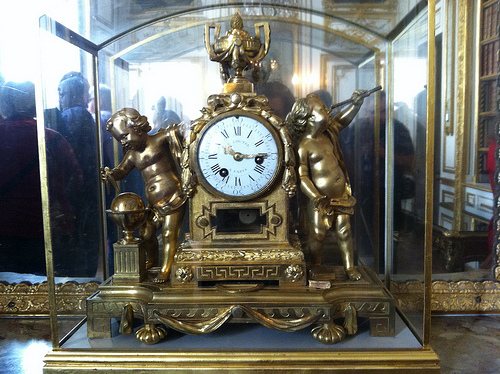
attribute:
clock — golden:
[169, 99, 302, 287]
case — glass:
[23, 0, 441, 372]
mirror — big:
[0, 0, 490, 299]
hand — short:
[214, 140, 233, 154]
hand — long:
[241, 150, 274, 166]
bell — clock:
[231, 207, 268, 229]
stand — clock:
[64, 235, 404, 345]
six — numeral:
[229, 171, 247, 190]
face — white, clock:
[191, 129, 284, 191]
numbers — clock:
[204, 126, 279, 198]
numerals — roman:
[194, 122, 284, 190]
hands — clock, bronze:
[220, 142, 267, 159]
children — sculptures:
[118, 119, 203, 267]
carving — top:
[200, 20, 280, 79]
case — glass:
[456, 320, 482, 355]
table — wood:
[441, 312, 482, 361]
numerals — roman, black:
[210, 135, 279, 185]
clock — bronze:
[114, 42, 413, 350]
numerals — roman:
[208, 125, 260, 176]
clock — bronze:
[79, 8, 420, 345]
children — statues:
[113, 109, 203, 255]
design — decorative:
[190, 254, 290, 277]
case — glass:
[40, 0, 433, 354]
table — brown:
[441, 300, 479, 363]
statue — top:
[196, 16, 286, 81]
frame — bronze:
[415, 189, 455, 347]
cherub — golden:
[105, 110, 198, 271]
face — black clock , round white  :
[208, 130, 278, 180]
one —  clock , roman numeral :
[243, 126, 257, 143]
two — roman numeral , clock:
[252, 137, 270, 155]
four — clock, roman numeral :
[248, 156, 276, 175]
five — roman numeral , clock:
[245, 175, 269, 189]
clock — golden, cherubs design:
[140, 37, 385, 324]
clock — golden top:
[175, 110, 291, 216]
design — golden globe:
[174, 205, 304, 258]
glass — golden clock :
[219, 144, 259, 169]